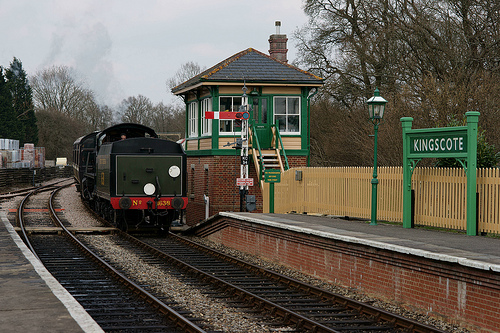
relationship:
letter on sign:
[448, 133, 471, 159] [394, 101, 489, 193]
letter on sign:
[449, 130, 460, 160] [391, 92, 488, 237]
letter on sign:
[443, 131, 455, 156] [391, 92, 488, 237]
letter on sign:
[432, 128, 450, 160] [392, 109, 489, 244]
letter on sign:
[426, 137, 436, 159] [387, 97, 496, 241]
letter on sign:
[425, 134, 437, 159] [392, 109, 489, 244]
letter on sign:
[426, 138, 436, 150] [391, 92, 488, 237]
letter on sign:
[411, 139, 419, 152] [394, 102, 491, 242]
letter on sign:
[407, 132, 426, 158] [395, 97, 484, 240]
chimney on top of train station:
[267, 18, 287, 67] [169, 46, 325, 220]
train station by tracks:
[174, 20, 321, 219] [14, 163, 451, 331]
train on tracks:
[68, 121, 194, 235] [76, 179, 438, 331]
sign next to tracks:
[398, 111, 483, 239] [14, 163, 451, 331]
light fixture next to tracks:
[362, 84, 387, 230] [14, 163, 451, 331]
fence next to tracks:
[262, 160, 498, 236] [14, 163, 451, 331]